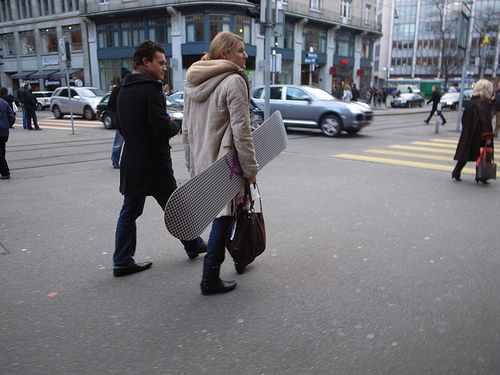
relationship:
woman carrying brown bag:
[450, 79, 493, 186] [477, 145, 499, 182]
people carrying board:
[180, 32, 267, 296] [162, 104, 291, 241]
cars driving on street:
[46, 79, 361, 138] [0, 111, 498, 373]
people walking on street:
[99, 30, 336, 300] [0, 111, 497, 374]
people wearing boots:
[180, 32, 267, 296] [197, 265, 243, 298]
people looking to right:
[180, 32, 267, 296] [348, 5, 498, 373]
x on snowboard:
[222, 149, 242, 182] [157, 103, 296, 251]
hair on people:
[204, 27, 248, 77] [180, 32, 267, 296]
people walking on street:
[180, 32, 267, 296] [0, 111, 498, 373]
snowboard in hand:
[163, 109, 288, 241] [231, 148, 261, 195]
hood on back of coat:
[179, 57, 241, 81] [174, 53, 262, 191]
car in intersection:
[247, 79, 376, 136] [9, 88, 479, 340]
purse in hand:
[235, 192, 297, 272] [235, 157, 261, 183]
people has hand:
[180, 32, 267, 296] [235, 157, 261, 183]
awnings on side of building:
[13, 64, 85, 85] [4, 5, 92, 93]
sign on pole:
[58, 35, 77, 135] [59, 37, 74, 64]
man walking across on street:
[422, 85, 448, 126] [14, 77, 484, 365]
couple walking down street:
[118, 40, 275, 286] [21, 153, 497, 277]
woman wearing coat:
[450, 79, 493, 186] [453, 96, 492, 160]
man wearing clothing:
[112, 38, 208, 277] [112, 71, 199, 260]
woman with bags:
[452, 70, 499, 190] [475, 137, 500, 189]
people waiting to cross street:
[13, 82, 44, 132] [41, 105, 110, 138]